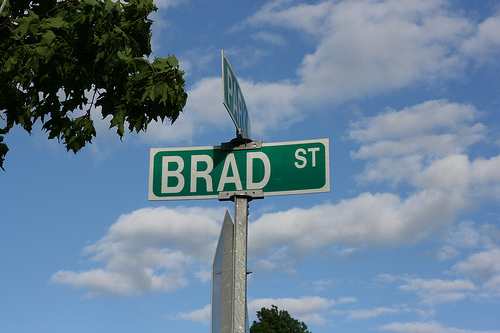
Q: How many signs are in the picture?
A: Two.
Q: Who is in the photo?
A: No one.